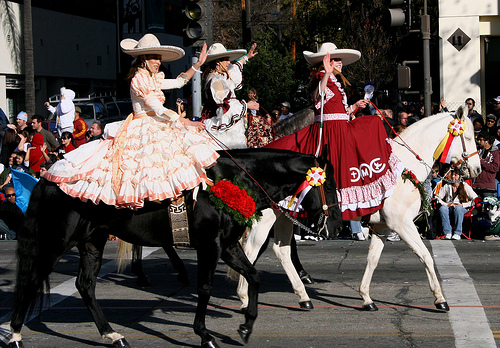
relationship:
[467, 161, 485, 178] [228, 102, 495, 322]
nose of horse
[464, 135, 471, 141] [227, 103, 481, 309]
eye of horse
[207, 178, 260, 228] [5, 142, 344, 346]
flowers on horse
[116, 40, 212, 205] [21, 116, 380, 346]
person riding horse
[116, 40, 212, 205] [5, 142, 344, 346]
person on horse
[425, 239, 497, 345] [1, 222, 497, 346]
line across road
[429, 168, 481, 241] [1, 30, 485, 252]
person along parade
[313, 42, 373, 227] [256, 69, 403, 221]
rider wearing mexican dress.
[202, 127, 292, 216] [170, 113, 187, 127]
reign in hand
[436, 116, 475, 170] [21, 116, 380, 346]
bridle on horse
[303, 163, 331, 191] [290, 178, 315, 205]
flower decoration on horse bridle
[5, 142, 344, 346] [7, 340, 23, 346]
horse has hoof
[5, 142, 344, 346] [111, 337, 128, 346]
horse has hoof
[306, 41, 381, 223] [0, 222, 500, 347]
rider along road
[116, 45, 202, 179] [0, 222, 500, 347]
person along road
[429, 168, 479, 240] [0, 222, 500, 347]
person along road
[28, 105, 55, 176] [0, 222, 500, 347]
person along road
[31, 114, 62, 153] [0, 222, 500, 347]
person along road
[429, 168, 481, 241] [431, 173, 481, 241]
person sitting in chair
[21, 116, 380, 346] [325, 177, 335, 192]
horse has a right eye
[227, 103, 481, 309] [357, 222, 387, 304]
horse has a leg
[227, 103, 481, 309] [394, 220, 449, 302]
horse has a leg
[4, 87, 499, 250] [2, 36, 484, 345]
spectators watching a parade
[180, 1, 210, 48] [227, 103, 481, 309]
traffic light next to horse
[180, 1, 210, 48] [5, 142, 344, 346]
traffic light next to horse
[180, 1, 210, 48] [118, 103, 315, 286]
traffic light next to horse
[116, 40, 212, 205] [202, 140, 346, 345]
person riding a horse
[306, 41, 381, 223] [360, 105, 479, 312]
rider riding a horse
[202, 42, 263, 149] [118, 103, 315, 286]
woman riding a horse